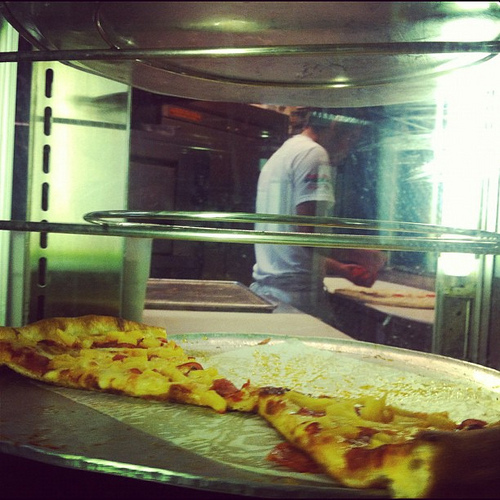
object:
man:
[248, 105, 383, 328]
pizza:
[258, 387, 500, 500]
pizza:
[0, 316, 260, 414]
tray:
[0, 332, 500, 500]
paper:
[42, 335, 500, 493]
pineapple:
[287, 391, 333, 411]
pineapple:
[117, 335, 137, 346]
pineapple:
[201, 388, 227, 414]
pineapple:
[425, 411, 458, 431]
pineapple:
[56, 326, 77, 346]